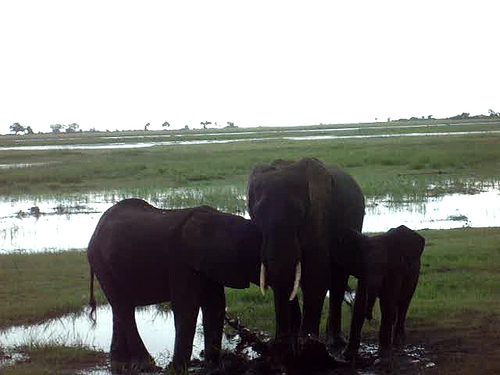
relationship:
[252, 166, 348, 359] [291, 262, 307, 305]
elephant has tusk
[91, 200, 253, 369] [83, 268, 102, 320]
elephant has tail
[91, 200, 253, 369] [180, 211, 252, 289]
elephant has ear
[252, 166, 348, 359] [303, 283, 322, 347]
elephant has leg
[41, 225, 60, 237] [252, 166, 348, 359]
water behind elephant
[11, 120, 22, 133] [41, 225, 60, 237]
tree near water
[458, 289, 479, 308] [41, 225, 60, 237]
grass near water